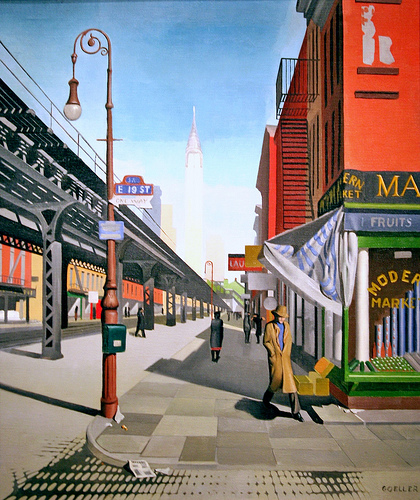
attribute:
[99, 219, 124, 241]
sign — blue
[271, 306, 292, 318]
hat — brown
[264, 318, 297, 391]
coat — lightbrown, long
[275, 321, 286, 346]
shirt — blue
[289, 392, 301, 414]
pants — tan, grey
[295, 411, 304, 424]
shoe — black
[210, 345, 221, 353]
dress — red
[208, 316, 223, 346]
coat — long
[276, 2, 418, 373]
building — red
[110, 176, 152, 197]
street sign — red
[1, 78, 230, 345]
traintracks — gray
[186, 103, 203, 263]
empire building — white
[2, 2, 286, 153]
sky — blue, cloudy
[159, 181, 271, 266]
clouds — white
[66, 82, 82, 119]
light — off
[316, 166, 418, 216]
sign — black, gold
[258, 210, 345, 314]
canopy — stripped